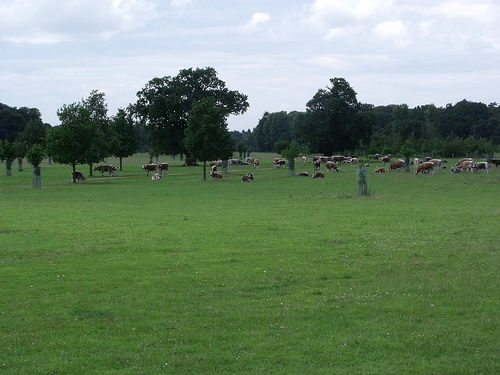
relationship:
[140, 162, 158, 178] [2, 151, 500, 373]
cow on field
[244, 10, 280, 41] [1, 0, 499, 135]
cloud in sky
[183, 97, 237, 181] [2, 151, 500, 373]
tree on field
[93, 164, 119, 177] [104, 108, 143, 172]
cow next to tree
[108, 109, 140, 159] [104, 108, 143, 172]
leaves on tree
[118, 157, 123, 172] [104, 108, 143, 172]
trunk of tree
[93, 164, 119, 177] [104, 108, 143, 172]
cow under tree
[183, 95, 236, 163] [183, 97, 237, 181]
leaves on tree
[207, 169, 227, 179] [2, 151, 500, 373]
cow on field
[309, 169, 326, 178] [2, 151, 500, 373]
animal on field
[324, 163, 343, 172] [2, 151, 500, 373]
animal on field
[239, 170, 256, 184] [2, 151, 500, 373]
animal on field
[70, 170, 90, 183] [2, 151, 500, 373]
cow on field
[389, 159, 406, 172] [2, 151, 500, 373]
cow on field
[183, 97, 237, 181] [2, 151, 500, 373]
tree in field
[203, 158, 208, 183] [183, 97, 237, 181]
trunk of tree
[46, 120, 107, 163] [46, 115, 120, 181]
leaves on tree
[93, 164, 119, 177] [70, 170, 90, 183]
cow next to cow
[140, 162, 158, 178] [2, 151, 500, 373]
cow in field